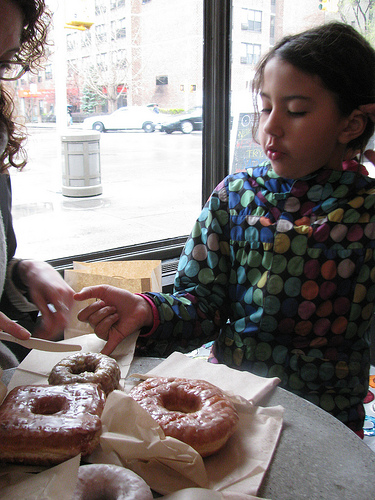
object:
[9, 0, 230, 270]
window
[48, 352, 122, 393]
donut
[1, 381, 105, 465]
donut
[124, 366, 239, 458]
donut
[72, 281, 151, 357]
hand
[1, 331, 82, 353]
knife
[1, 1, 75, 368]
adult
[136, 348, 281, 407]
napkin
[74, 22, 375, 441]
girl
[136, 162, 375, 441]
blouse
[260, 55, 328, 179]
face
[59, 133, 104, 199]
trash can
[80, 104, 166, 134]
car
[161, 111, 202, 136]
car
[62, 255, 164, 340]
paper bag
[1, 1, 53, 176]
hair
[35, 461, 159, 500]
donuts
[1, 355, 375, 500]
table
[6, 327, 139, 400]
napkin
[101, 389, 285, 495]
napkin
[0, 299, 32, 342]
hand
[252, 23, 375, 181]
head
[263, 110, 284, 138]
nose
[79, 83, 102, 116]
tree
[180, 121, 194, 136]
tire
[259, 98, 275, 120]
eyes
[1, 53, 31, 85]
eyeglasses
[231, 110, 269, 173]
advertising board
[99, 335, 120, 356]
finger